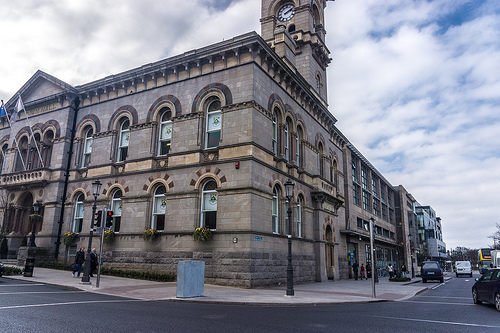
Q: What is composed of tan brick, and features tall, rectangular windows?
A: A large building, filling most of a city block.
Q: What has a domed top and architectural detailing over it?
A: All of the visible windows on the front, as well as part of the right side, of a city building.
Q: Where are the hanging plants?
A: Below the windows, on the lowest level of the front section of a tan, city building.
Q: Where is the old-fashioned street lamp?
A: On the corner of the sidewalk, on a city block, in front of a large, tan building.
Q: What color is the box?
A: Gray.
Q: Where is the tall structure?
A: On top of building.